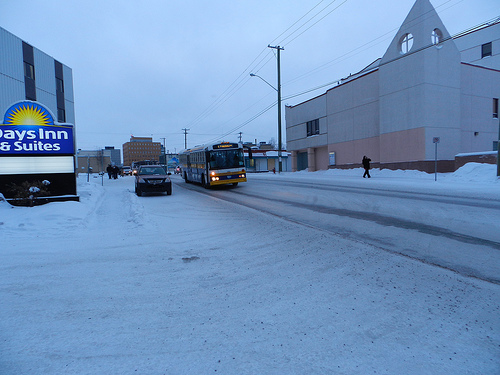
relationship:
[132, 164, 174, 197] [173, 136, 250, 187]
suv next to bus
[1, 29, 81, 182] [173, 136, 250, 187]
hotel next to bus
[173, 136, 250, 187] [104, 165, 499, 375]
bus driving down road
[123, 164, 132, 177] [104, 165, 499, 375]
vehicle on side of road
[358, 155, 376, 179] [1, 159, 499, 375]
person walking in snow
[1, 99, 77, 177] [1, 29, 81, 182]
sign for hotel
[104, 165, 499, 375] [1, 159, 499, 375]
road covered in snow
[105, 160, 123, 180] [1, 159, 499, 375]
people walking in snow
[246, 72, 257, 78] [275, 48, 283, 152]
light attached to pole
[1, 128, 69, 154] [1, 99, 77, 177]
writing on sign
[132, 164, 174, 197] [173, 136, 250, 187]
suv to left of bus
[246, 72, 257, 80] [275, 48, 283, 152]
light attached to pole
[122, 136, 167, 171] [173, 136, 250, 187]
building behind bus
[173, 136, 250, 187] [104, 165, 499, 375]
bus on road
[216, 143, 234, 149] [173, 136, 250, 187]
word on top of bus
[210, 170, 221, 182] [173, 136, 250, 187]
lights on front of bus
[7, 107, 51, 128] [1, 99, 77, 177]
sun on sign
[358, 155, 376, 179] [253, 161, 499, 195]
person on sidewalk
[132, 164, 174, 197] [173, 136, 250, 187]
suv on side of bus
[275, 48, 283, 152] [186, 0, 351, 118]
pole with wires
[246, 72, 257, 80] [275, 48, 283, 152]
light on pole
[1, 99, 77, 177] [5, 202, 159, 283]
sign in snow